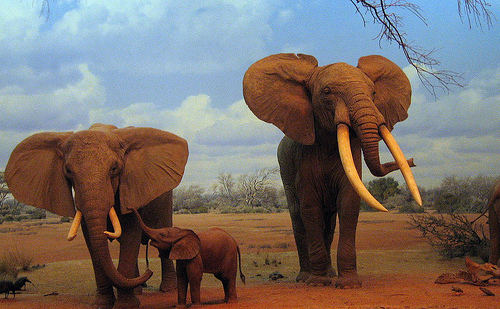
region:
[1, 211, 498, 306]
red dirt on ground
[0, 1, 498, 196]
blue sky with white clouds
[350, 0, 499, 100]
bare branch hanging over elephant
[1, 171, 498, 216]
green, dry trees in the distance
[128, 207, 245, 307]
baby elephant in the middle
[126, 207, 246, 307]
red baby elephant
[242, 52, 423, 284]
large red elephant on the right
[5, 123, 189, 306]
medium sized red elephant on the left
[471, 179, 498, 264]
behind of elephant on the right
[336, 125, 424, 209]
large, cream colored horns of elephant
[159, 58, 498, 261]
the elephant has tusk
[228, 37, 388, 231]
the elephant has tusk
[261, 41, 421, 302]
the elephant has tusk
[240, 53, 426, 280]
gray elephant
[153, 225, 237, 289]
gray elephant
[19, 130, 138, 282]
gray elephant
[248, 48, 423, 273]
large gray elephant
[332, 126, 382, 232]
white tusk of large gray elephant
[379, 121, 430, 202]
white tusk of large gray elephant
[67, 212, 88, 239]
white tusk of large gray elephant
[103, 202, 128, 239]
white tusk of large gray elephant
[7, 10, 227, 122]
white clouds against blue sky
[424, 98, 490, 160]
white clouds against blue sky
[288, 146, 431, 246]
white tusks on the elephant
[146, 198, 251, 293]
baby elephant next to adult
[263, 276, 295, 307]
red ground next to elephants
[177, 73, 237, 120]
clouds in the sky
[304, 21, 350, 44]
blue sky above the clouds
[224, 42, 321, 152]
ear of the elephant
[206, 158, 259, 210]
trees behind the elephants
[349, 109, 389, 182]
trunk of the elephant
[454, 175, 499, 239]
tail of the elephant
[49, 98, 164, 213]
head of the elephant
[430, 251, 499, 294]
White bones on the ground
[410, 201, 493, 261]
pile of brown twigs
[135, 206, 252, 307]
one baby elephant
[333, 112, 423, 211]
Husks coming from elephant's nose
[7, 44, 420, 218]
two elephants with ears stretched out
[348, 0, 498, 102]
partial view of tree branches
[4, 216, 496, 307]
Orange and brown ground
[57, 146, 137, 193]
Left elephant's eyes looking at the camera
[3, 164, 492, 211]
Short greenish gray bushes in background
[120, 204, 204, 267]
baby elephant's head turned up